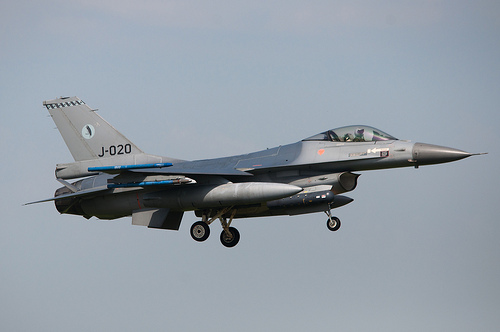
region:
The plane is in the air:
[11, 37, 491, 317]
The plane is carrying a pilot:
[26, 60, 486, 315]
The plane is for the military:
[0, 26, 478, 299]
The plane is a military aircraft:
[7, 63, 472, 299]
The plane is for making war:
[20, 35, 490, 295]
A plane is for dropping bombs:
[11, 67, 481, 317]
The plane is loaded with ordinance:
[8, 47, 478, 298]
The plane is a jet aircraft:
[15, 62, 495, 290]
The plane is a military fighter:
[0, 50, 496, 275]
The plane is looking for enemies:
[11, 58, 498, 292]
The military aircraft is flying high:
[7, 18, 489, 295]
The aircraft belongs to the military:
[7, 45, 498, 282]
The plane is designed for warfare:
[6, 65, 498, 316]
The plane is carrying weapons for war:
[12, 68, 498, 323]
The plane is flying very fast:
[6, 27, 497, 307]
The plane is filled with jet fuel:
[0, 30, 498, 300]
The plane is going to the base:
[20, 47, 498, 264]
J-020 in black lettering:
[98, 139, 132, 159]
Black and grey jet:
[23, 79, 485, 242]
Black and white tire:
[327, 214, 345, 236]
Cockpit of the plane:
[302, 118, 408, 142]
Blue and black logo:
[79, 118, 97, 142]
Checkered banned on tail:
[39, 100, 89, 109]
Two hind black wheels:
[191, 215, 253, 249]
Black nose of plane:
[411, 129, 488, 173]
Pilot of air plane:
[354, 123, 364, 140]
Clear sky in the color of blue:
[1, 0, 495, 329]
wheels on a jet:
[185, 197, 267, 263]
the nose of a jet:
[367, 95, 468, 185]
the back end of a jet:
[37, 51, 199, 193]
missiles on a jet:
[94, 143, 188, 222]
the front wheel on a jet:
[306, 183, 388, 240]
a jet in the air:
[74, 96, 374, 263]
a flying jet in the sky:
[31, 85, 441, 295]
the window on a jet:
[294, 100, 403, 151]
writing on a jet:
[81, 106, 144, 244]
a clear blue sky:
[214, 42, 379, 137]